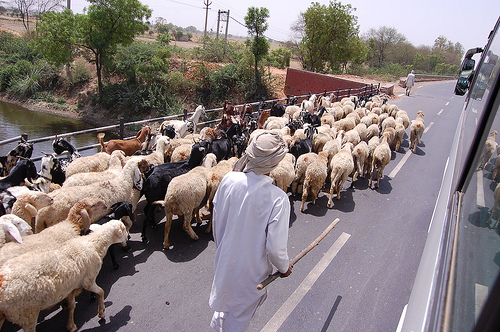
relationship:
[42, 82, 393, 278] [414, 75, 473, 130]
sheep aside road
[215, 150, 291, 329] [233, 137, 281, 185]
man wears turban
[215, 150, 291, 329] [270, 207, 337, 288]
man carries stick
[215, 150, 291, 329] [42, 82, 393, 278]
man beside sheep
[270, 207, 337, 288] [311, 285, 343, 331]
stick has shadow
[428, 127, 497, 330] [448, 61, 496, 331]
windows aside bus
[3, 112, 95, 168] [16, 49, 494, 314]
river below bridge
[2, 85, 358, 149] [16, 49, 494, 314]
guard rail near bridge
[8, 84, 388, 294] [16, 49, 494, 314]
goats on bridge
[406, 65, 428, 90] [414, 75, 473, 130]
man on road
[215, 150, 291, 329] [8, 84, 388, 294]
man near goats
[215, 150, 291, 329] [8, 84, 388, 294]
man walks with goats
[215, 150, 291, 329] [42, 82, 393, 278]
man walks with sheep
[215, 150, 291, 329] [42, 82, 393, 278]
man with sheep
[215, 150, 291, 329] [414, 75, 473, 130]
man on road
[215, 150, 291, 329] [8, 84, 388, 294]
man walking with goats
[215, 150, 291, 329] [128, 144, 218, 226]
man walking with goat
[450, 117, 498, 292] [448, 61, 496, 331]
mirror on bus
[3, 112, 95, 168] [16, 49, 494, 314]
water under bridge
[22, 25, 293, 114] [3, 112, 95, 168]
bushes near water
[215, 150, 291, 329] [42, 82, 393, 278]
man herds sheep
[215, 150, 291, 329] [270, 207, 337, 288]
man has stick